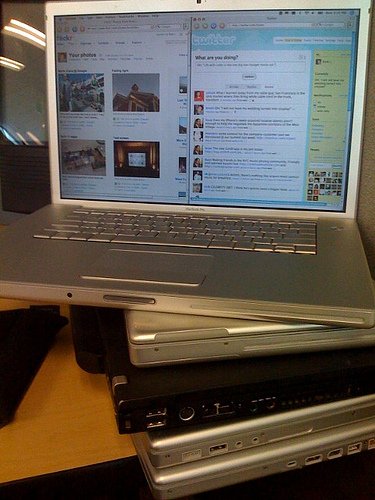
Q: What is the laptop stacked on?
A: Laptops.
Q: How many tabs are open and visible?
A: 2.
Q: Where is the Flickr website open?
A: On the left.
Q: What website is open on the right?
A: Twitter.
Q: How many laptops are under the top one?
A: 4.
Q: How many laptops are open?
A: 1.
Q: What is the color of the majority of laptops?
A: Silver.